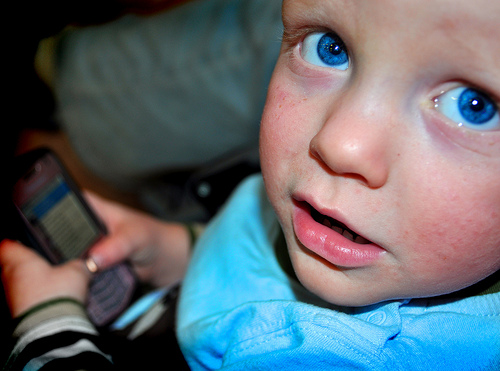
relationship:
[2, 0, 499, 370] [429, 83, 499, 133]
boy has eye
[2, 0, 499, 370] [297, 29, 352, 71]
boy has eye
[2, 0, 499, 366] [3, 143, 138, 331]
boy holding cellphone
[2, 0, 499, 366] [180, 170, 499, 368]
boy wearing shirt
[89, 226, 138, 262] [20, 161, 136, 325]
finger on screen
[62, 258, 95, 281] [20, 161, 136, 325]
finger on screen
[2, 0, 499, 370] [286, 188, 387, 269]
boy has mouth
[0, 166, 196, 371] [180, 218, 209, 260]
shirt has sleeve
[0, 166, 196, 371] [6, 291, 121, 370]
shirt has sleeve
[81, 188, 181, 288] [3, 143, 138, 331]
hand holding cellphone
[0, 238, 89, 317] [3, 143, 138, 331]
hand holding cellphone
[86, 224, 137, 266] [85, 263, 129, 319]
thumb resting on keyboard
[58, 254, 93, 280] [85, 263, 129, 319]
thumb resting on keyboard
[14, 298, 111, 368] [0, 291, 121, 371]
stripes on sleeve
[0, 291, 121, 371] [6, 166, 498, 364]
sleeve of shirt